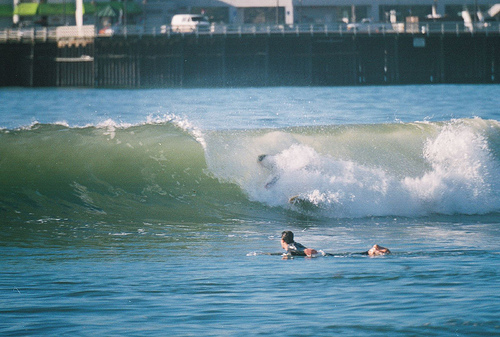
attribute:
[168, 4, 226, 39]
van — white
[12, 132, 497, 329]
water — blue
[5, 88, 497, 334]
water — green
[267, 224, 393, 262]
person — enjoying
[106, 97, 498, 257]
wave — crashing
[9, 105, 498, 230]
wave — crashing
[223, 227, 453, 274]
person — wet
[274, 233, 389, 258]
person — swimming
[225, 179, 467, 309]
person — day-outing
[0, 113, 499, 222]
wave — crashing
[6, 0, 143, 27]
umbrellas — green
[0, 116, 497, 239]
wave — big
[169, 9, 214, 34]
van — white 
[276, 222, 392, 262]
person — vacationing